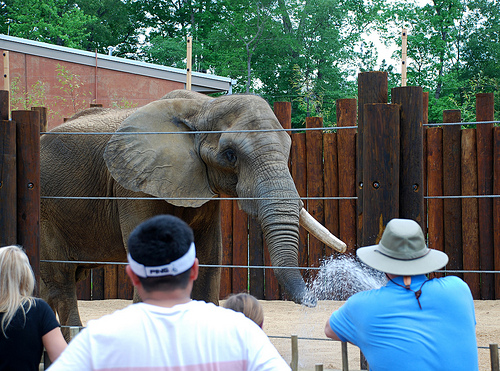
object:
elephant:
[40, 88, 347, 343]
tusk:
[299, 206, 346, 255]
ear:
[102, 98, 219, 208]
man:
[43, 214, 290, 369]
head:
[125, 214, 199, 301]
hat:
[355, 217, 448, 277]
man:
[323, 217, 479, 370]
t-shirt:
[327, 272, 479, 370]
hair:
[0, 244, 39, 340]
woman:
[0, 244, 68, 370]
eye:
[223, 149, 237, 163]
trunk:
[235, 163, 319, 309]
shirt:
[43, 297, 293, 370]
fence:
[0, 69, 499, 301]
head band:
[127, 241, 196, 278]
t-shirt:
[0, 297, 62, 370]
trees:
[0, 0, 499, 126]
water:
[301, 251, 387, 307]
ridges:
[259, 207, 301, 258]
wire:
[41, 193, 499, 199]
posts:
[1, 71, 428, 299]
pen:
[0, 71, 499, 370]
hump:
[69, 88, 212, 121]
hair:
[222, 291, 264, 328]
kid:
[220, 293, 265, 329]